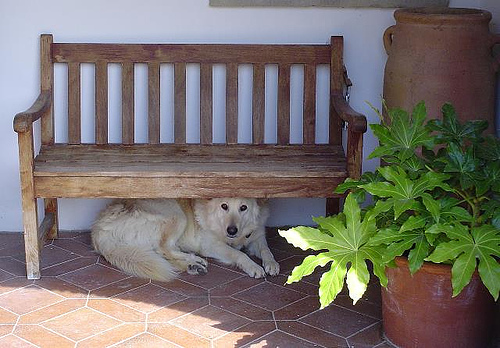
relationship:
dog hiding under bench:
[86, 198, 283, 284] [14, 34, 367, 279]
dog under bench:
[86, 198, 283, 284] [26, 47, 368, 225]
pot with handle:
[381, 7, 499, 167] [381, 21, 396, 56]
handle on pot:
[382, 23, 396, 51] [381, 7, 500, 167]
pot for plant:
[376, 245, 494, 346] [272, 90, 498, 315]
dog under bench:
[91, 194, 278, 284] [14, 34, 367, 279]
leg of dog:
[198, 233, 263, 280] [91, 194, 278, 284]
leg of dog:
[248, 234, 278, 274] [91, 194, 278, 284]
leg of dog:
[166, 243, 206, 275] [91, 194, 278, 284]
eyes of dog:
[218, 201, 250, 213] [24, 171, 306, 289]